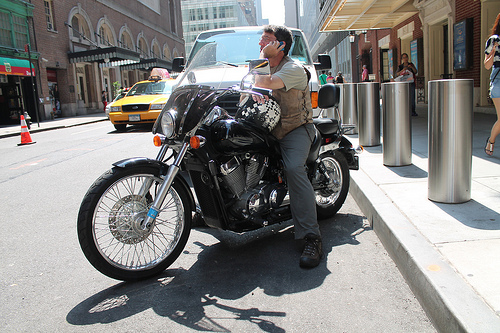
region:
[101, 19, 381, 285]
man riding a motorcycle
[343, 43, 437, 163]
people walking at the sidwalk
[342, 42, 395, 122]
people walking at the sidwalk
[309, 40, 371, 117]
people walking at the sidwalk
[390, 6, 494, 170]
people walking at the sidwalk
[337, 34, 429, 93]
people walking at the sidwalk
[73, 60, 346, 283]
A motor bike in the photo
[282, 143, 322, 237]
A gray trouser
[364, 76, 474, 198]
barriers on the side walk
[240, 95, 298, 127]
A helmet in the photo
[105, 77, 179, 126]
A cab in the background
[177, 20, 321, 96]
A white vehicle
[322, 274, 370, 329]
A road with tarmac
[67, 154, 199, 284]
A motor bike wheel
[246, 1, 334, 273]
A person sitting on a bike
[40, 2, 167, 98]
A building in the city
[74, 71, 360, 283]
a black and chrome motorcycle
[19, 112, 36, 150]
orange and white cone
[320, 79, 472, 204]
five rounded sliver rods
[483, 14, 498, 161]
a woman with blonde hair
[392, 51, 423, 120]
a woman standing on side walk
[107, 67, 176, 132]
a yellow taxi cab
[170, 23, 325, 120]
a small white truck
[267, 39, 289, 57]
a man talking on cell phone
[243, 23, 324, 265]
a man sitting on a motorcycle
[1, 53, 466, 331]
a wide gray street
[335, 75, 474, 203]
metal canisters in a row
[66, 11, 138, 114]
awning over front of doorway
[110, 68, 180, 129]
front of yellow cab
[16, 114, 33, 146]
white and orange pylon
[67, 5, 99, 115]
arch design over doorway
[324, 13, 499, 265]
people walking on sidewalk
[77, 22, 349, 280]
man sitting on motorbike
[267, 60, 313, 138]
vest over short sleeve shirt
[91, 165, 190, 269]
spokes of bike tire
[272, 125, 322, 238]
gray pants on leg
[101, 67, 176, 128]
Most cities have yellow cabs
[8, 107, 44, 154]
orange traffic cone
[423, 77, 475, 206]
traffic barrier to protect sidewalk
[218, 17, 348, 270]
man on a motorcycle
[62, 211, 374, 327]
shadow of motorcycle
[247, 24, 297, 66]
man's head without helmet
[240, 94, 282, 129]
helmet to be worn when riding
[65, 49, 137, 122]
awning over building entrance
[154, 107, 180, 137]
headlight on motorcycle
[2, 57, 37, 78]
red and green awning